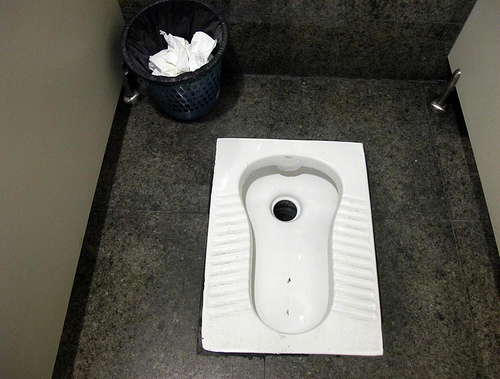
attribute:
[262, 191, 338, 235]
hole —  flush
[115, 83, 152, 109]
handle — white, black , wastebasket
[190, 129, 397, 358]
floor — white flush 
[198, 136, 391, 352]
flush — water 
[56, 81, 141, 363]
wall — black border ,  bottom 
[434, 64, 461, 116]
pipe — silver 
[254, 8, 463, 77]
wall — gray black 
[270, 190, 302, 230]
circle — dark black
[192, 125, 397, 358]
square — ong white ceramic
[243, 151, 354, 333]
oval — long white ceramic 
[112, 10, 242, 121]
can — short black trash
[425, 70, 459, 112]
object — short silver 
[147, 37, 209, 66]
papers — white , trash can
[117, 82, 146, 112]
object — small shiny silver 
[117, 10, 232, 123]
bag — black , trash can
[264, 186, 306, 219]
holes — small black , trash can